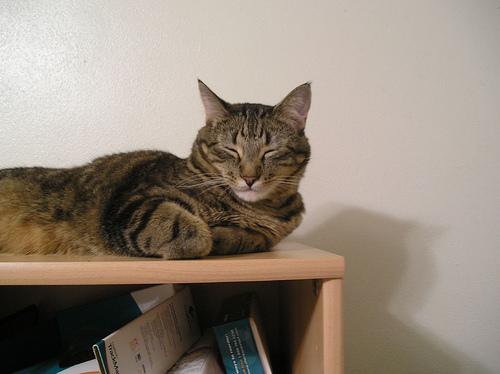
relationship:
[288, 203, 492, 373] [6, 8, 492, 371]
shadow casted on wall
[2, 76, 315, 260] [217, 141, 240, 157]
cat closing eye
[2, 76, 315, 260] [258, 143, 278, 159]
cat closing eye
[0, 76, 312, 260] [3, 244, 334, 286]
cat on top of shelf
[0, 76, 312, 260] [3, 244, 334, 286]
cat sleeping on shelf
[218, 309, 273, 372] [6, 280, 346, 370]
box on top of shelf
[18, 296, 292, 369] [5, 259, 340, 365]
books are on top of shelf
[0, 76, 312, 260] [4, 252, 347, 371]
cat on top of bookcase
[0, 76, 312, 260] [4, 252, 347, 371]
cat lying on bookcase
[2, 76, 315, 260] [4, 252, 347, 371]
cat relaxing on bookcase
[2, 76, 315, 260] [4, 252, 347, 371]
cat lounging on bookcase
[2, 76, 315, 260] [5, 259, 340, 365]
cat sleeping on shelf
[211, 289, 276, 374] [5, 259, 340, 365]
box on shelf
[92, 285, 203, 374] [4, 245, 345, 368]
books on shelf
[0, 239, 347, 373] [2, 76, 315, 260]
bookcase under cat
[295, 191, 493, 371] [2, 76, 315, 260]
shadow of cat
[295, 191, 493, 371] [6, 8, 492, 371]
shadow on wall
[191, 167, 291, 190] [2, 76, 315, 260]
white whiskers on cat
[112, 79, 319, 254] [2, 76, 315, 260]
black stripes on cat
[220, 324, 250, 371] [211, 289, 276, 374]
words on side of box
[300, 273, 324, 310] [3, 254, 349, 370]
metal bracket in shelf